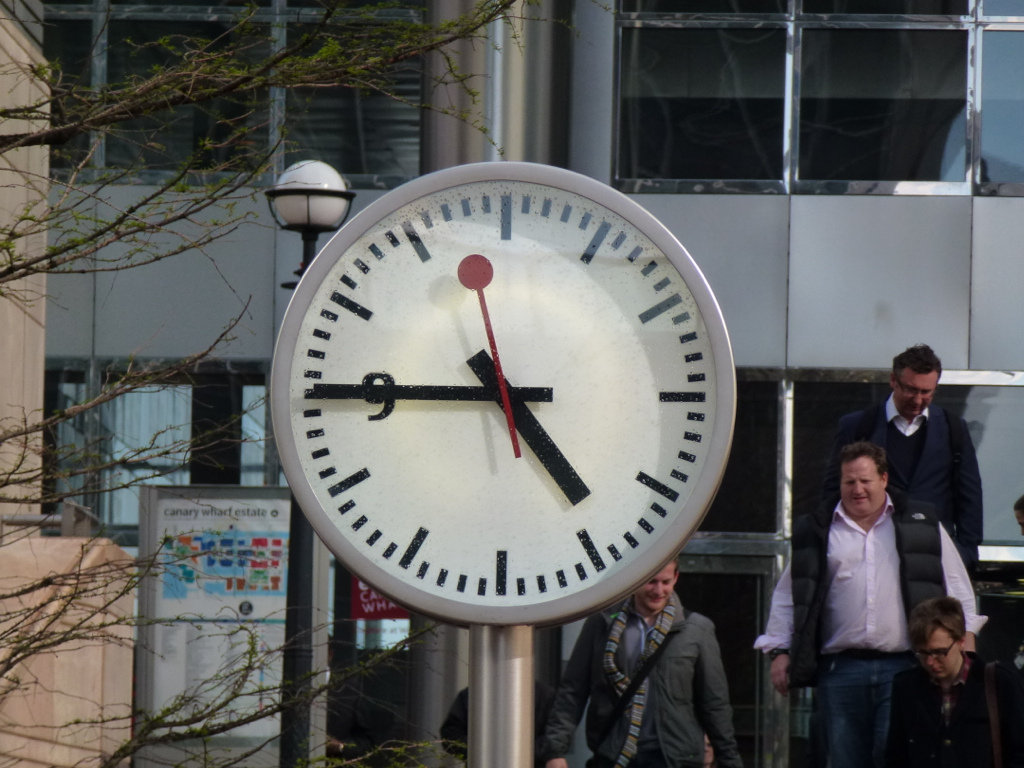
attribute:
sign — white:
[105, 468, 324, 738]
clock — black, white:
[268, 158, 736, 629]